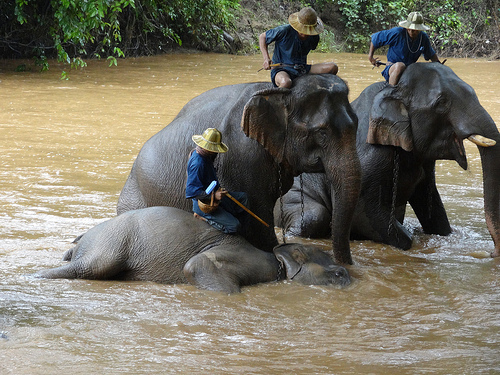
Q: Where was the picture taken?
A: A river.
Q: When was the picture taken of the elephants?
A: Daytime.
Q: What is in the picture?
A: Elephants.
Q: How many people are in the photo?
A: Three.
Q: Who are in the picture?
A: Men.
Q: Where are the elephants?
A: In the water.